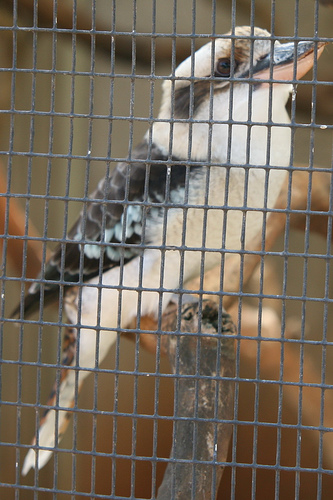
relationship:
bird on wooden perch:
[0, 25, 328, 476] [1, 155, 332, 498]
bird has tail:
[0, 25, 328, 476] [18, 326, 123, 479]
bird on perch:
[0, 25, 328, 476] [150, 298, 251, 498]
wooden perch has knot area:
[1, 155, 332, 498] [171, 295, 247, 339]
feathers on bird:
[91, 46, 290, 341] [0, 25, 328, 476]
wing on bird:
[6, 139, 190, 319] [0, 25, 328, 476]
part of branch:
[171, 355, 237, 421] [162, 292, 239, 499]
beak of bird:
[254, 43, 323, 87] [0, 25, 328, 476]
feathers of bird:
[15, 26, 326, 488] [0, 25, 328, 476]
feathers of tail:
[15, 26, 326, 488] [13, 263, 138, 471]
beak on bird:
[254, 41, 326, 85] [0, 25, 328, 476]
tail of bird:
[38, 451, 51, 470] [0, 25, 328, 476]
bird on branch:
[0, 25, 328, 476] [0, 173, 330, 497]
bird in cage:
[0, 25, 328, 476] [2, 3, 322, 489]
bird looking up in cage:
[0, 25, 328, 476] [2, 3, 322, 489]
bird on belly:
[0, 25, 328, 476] [195, 113, 292, 269]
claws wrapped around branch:
[174, 287, 215, 314] [117, 293, 237, 498]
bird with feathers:
[0, 25, 328, 476] [15, 26, 326, 488]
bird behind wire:
[0, 25, 328, 476] [90, 52, 133, 130]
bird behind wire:
[167, 153, 257, 238] [101, 84, 147, 128]